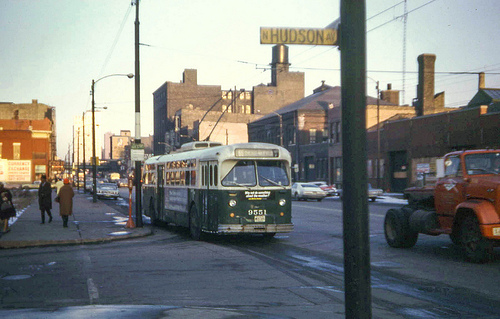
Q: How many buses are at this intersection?
A: 1.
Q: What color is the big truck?
A: Orange.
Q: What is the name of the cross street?
A: Hudson Ave.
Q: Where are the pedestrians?
A: On the sidewalk.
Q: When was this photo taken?
A: Daytime.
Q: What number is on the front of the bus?
A: 9551.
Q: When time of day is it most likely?
A: Morning.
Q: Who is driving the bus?
A: Bus Driver.